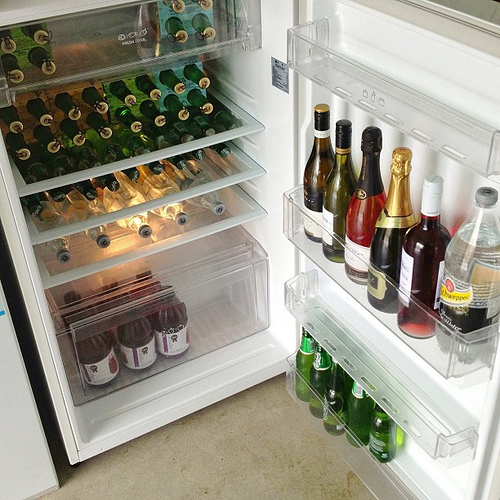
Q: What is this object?
A: Small refrigerator.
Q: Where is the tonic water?
A: On a shelf in the door.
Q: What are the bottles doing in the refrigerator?
A: Getting cold.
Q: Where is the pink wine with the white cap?
A: On the refrigerator door.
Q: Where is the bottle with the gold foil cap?
A: In the door.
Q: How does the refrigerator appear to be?
A: Clean.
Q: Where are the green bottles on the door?
A: On the bottom shelf.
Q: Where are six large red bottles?
A: On the bottom of the refrigerator in a drawer.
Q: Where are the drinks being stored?
A: In a refrigerator.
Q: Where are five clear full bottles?
A: On the fourth shelf.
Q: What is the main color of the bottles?
A: Green.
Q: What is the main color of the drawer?
A: Clear.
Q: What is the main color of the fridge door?
A: White.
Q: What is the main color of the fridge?
A: White.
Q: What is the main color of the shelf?
A: White.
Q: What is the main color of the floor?
A: Brown.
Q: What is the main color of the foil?
A: Gold.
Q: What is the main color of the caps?
A: Yellow.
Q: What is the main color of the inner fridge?
A: White.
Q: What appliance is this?
A: Fridge.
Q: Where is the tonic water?
A: On the door shelf.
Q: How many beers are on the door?
A: 6.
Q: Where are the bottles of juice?
A: Bottom drawer.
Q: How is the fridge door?
A: Open.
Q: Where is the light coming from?
A: Inside the fridge.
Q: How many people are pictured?
A: Zero.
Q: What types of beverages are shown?
A: Alcoholic.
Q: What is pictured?
A: Refrigerator.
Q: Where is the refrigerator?
A: Kitchen.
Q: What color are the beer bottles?
A: Green.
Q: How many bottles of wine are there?
A: Five.